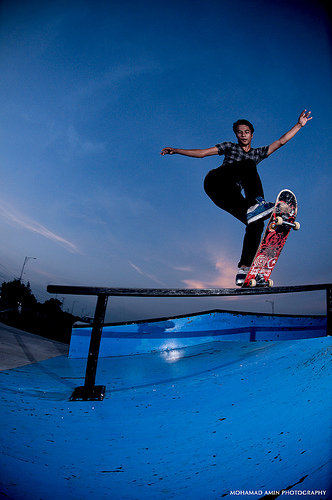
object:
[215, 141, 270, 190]
top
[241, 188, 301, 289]
skateboard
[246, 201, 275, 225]
feet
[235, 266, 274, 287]
feet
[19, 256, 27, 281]
pole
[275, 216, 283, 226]
wheel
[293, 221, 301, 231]
wheel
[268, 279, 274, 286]
wheel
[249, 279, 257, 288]
wheel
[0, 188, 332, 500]
skate park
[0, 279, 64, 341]
trees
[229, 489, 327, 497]
copyright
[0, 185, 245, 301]
clouds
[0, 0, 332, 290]
sky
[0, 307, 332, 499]
ramp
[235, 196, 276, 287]
shoes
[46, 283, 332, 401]
seat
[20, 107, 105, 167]
cloud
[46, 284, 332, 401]
rail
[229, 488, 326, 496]
bottom right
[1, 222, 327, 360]
background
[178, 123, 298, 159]
arms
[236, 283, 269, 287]
sole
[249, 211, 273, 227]
sole